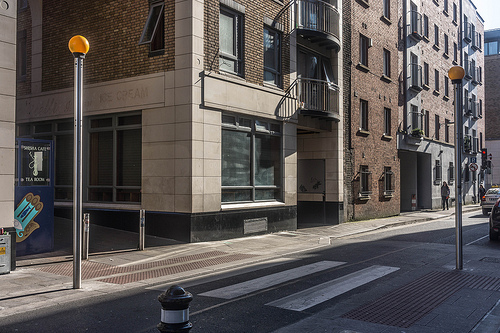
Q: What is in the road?
A: A cross walk.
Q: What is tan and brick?
A: A building.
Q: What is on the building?
A: Windows.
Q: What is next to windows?
A: Balconies.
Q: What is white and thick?
A: Lines on street.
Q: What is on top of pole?
A: Yellow ball.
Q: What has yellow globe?
A: Street light.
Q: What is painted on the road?
A: White lines.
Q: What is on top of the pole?
A: A light.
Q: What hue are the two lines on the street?
A: White.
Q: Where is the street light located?
A: The sidewalk.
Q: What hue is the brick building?
A: Tan.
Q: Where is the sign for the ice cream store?
A: On building.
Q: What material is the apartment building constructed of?
A: Brick.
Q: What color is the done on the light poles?
A: Yellow.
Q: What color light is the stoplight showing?
A: Red.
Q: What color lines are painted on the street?
A: White.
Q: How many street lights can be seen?
A: Two.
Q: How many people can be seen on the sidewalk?
A: Two.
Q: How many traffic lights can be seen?
A: One.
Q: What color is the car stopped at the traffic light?
A: White.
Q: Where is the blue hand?
A: On the billboard.